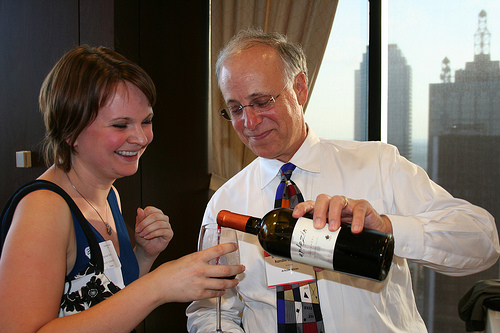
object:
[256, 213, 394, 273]
wine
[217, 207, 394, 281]
bottle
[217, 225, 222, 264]
wine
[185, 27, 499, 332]
man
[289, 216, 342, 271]
label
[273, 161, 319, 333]
tie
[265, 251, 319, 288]
nametag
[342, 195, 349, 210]
ring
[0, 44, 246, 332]
woman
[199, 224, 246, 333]
wineglass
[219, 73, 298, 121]
eyeglasses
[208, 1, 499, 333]
window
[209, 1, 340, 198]
curtain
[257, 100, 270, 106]
eye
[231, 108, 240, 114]
eye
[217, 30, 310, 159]
head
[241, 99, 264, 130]
nose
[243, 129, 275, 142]
mouth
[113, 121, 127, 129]
eye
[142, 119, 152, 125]
eye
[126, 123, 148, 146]
nose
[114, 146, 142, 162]
mouth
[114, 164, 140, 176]
chin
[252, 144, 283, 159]
chin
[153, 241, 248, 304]
hand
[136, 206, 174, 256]
hand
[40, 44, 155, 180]
head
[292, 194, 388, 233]
hand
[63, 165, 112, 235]
necklace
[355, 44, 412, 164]
building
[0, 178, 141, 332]
dress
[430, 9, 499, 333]
building